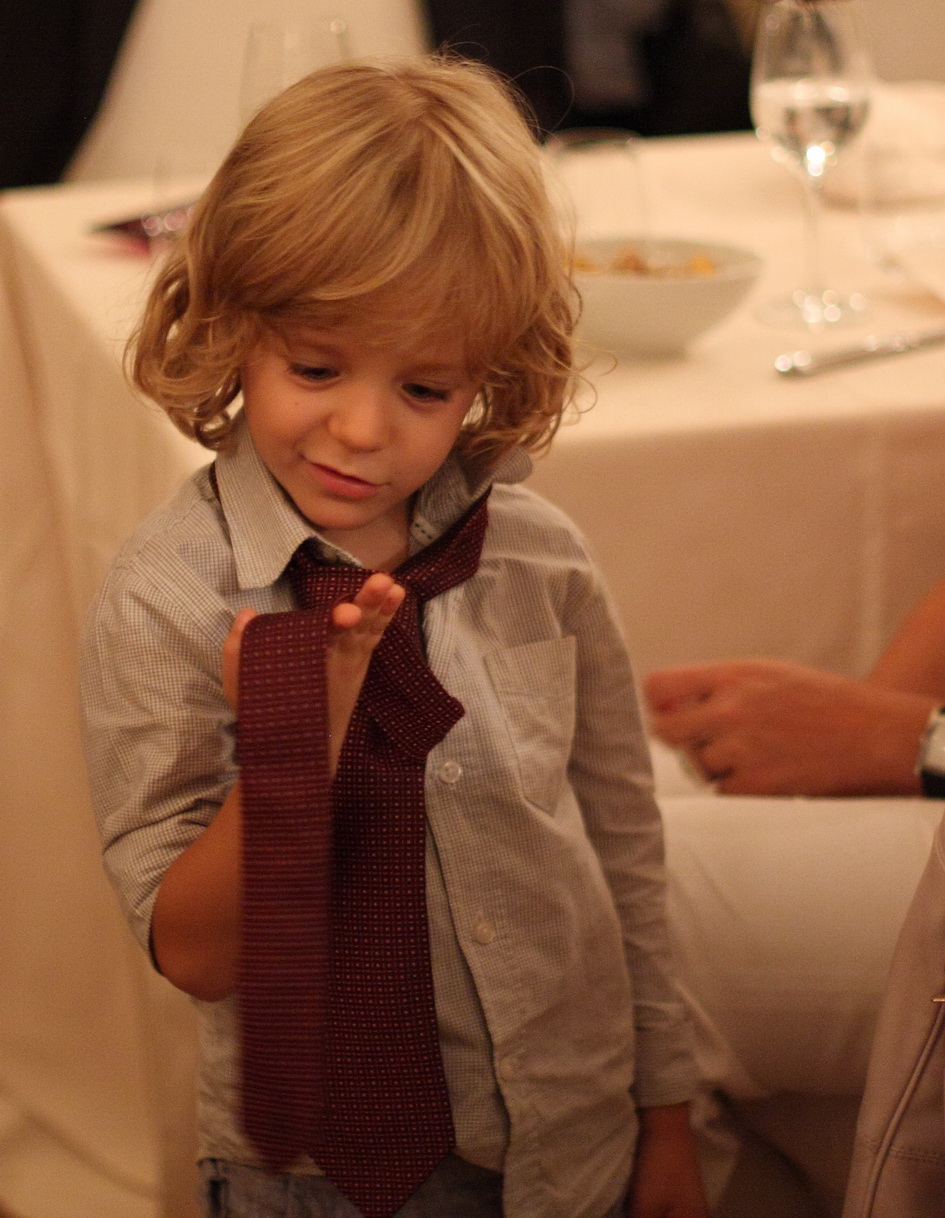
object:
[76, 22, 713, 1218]
boy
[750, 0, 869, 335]
glass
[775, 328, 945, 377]
knife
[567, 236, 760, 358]
bowl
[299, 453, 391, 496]
mouth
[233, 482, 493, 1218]
tie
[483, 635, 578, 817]
pocket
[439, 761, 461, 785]
button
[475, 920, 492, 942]
button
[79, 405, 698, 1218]
shirt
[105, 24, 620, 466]
hair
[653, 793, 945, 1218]
pants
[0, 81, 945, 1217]
table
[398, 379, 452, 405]
eye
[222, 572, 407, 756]
hand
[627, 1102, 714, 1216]
hand